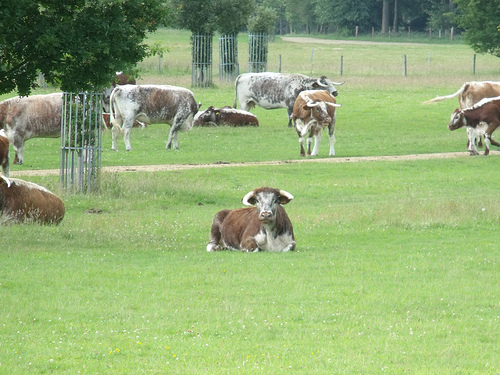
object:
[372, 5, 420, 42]
trees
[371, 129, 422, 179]
sky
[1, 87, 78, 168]
cow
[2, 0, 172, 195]
green tree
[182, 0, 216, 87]
green tree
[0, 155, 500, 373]
ground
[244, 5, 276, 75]
trees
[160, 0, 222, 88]
trees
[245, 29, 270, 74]
fence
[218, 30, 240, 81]
fence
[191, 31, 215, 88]
fence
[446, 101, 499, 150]
standing cow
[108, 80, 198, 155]
standing cow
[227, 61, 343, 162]
standing cow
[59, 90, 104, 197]
guard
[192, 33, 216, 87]
guard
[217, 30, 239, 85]
guard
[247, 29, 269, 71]
guard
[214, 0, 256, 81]
tree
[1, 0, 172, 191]
tree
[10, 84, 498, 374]
grass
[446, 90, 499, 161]
animal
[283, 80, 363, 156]
animal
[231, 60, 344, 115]
animal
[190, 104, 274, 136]
animal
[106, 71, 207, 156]
animal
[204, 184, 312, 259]
animal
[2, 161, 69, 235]
animal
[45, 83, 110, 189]
enclosure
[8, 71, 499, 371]
field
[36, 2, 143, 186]
branches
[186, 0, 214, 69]
branches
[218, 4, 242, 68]
branches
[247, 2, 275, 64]
branches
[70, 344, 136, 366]
flower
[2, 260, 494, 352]
pasture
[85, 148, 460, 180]
strip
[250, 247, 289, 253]
hoofs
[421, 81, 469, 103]
tail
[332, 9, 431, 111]
air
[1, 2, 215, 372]
left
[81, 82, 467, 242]
back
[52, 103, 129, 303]
trunks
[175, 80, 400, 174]
over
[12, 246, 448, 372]
direction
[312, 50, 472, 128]
fence